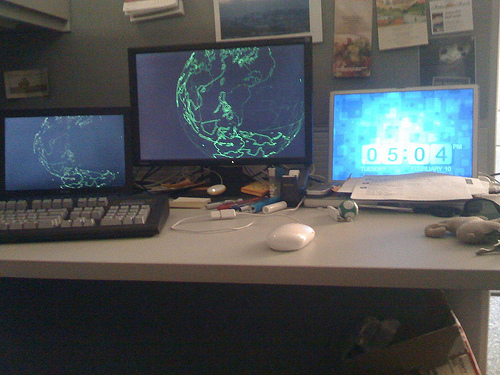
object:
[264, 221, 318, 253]
mouse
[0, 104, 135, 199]
monitor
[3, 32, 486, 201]
row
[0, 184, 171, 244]
keyboard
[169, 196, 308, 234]
wire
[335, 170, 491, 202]
paper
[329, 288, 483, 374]
box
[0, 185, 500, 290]
desk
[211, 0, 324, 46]
picture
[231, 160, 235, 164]
light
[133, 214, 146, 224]
keys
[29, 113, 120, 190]
globe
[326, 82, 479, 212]
computer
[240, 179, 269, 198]
post-it notes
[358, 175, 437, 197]
printing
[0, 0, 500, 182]
wall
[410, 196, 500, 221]
sunglasses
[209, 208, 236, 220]
white out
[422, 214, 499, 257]
elephant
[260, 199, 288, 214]
highlighter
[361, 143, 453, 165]
time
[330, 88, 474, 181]
screen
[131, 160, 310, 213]
junk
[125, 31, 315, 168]
monitor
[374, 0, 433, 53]
papers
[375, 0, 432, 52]
calendar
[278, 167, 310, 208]
tape dispenser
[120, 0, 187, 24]
bent paper